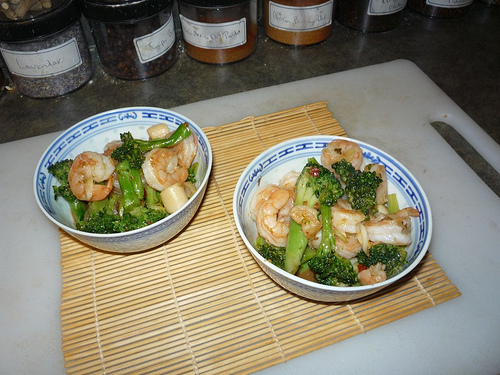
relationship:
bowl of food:
[32, 106, 211, 255] [48, 127, 194, 233]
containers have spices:
[1, 0, 94, 99] [83, 2, 178, 80]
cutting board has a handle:
[344, 59, 489, 137] [430, 119, 499, 213]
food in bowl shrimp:
[259, 140, 416, 282] [69, 150, 116, 203]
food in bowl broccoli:
[259, 140, 416, 282] [310, 206, 356, 288]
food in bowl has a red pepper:
[259, 140, 416, 282] [355, 262, 367, 272]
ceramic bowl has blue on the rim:
[232, 135, 432, 304] [385, 155, 421, 207]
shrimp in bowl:
[69, 150, 116, 203] [32, 106, 211, 255]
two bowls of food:
[232, 135, 432, 304] [48, 127, 194, 233]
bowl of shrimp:
[32, 106, 211, 255] [69, 150, 116, 203]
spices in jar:
[83, 2, 178, 80] [1, 0, 94, 99]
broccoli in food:
[310, 206, 356, 288] [48, 127, 194, 233]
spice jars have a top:
[1, 0, 94, 99] [82, 1, 178, 21]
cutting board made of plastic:
[344, 59, 489, 137] [2, 227, 59, 374]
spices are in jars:
[83, 2, 178, 80] [1, 0, 94, 99]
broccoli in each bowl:
[310, 206, 356, 288] [32, 106, 211, 255]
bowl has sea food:
[232, 135, 432, 304] [143, 135, 198, 189]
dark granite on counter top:
[438, 17, 499, 86] [419, 19, 497, 70]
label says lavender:
[1, 39, 82, 79] [14, 57, 65, 72]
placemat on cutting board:
[62, 247, 246, 374] [431, 80, 497, 375]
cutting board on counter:
[431, 80, 497, 375] [438, 17, 499, 86]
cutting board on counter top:
[344, 59, 489, 137] [419, 19, 497, 70]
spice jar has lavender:
[1, 0, 94, 99] [14, 57, 65, 72]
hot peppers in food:
[355, 262, 367, 272] [48, 127, 194, 233]